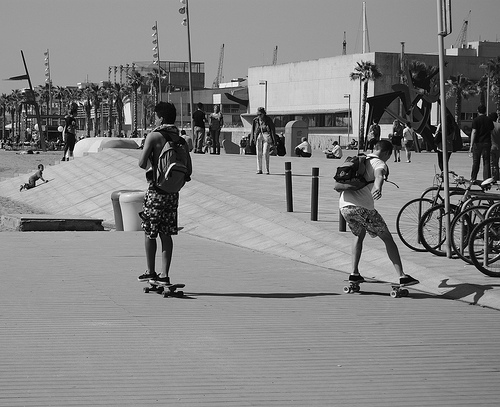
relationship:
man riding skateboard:
[137, 100, 192, 284] [142, 273, 188, 299]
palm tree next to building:
[77, 86, 92, 136] [242, 36, 499, 147]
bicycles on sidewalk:
[395, 170, 499, 276] [201, 151, 498, 300]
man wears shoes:
[137, 100, 192, 298] [138, 270, 169, 285]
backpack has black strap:
[149, 129, 192, 194] [158, 128, 170, 143]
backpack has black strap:
[149, 129, 192, 194] [178, 135, 186, 145]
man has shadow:
[137, 100, 192, 284] [174, 290, 341, 299]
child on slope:
[20, 162, 48, 189] [4, 148, 144, 228]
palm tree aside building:
[347, 54, 379, 151] [242, 36, 499, 147]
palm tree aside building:
[401, 41, 441, 148] [242, 36, 499, 147]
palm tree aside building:
[445, 71, 477, 139] [242, 36, 499, 147]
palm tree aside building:
[473, 51, 499, 121] [242, 36, 499, 147]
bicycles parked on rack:
[395, 170, 499, 276] [416, 187, 498, 266]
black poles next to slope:
[281, 158, 323, 222] [186, 185, 361, 275]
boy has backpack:
[330, 130, 417, 300] [335, 157, 367, 193]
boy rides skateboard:
[330, 130, 417, 300] [343, 272, 419, 292]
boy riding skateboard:
[333, 139, 419, 287] [342, 266, 432, 298]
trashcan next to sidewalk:
[110, 188, 143, 234] [0, 149, 498, 407]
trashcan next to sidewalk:
[110, 188, 140, 228] [0, 149, 498, 407]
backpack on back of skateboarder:
[153, 134, 195, 201] [131, 95, 202, 302]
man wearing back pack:
[137, 100, 192, 284] [115, 156, 211, 198]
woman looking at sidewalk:
[249, 104, 278, 176] [120, 149, 497, 288]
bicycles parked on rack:
[408, 176, 496, 274] [416, 187, 498, 266]